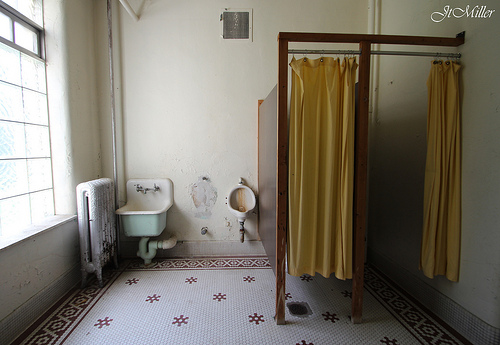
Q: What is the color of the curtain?
A: It is gold.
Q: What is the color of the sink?
A: It is green.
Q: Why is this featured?
A: To show old designs for toilet.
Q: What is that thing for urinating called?
A: It is urinal.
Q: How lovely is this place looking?
A: Not at all.